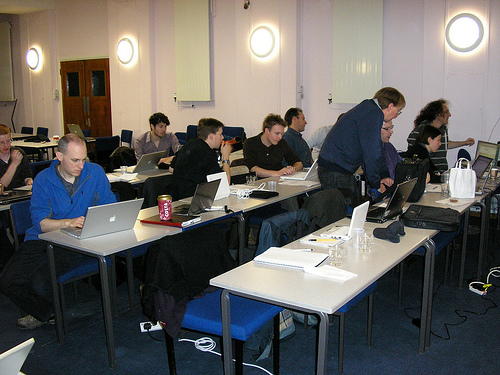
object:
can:
[156, 193, 174, 222]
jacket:
[296, 186, 349, 230]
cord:
[176, 335, 271, 374]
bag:
[446, 157, 477, 202]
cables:
[467, 278, 490, 295]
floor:
[4, 218, 499, 373]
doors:
[82, 57, 115, 137]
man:
[6, 133, 118, 331]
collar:
[280, 220, 309, 240]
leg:
[315, 317, 329, 375]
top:
[206, 218, 442, 317]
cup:
[487, 166, 497, 183]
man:
[133, 113, 178, 172]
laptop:
[320, 200, 369, 244]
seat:
[153, 286, 285, 373]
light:
[244, 20, 279, 66]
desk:
[206, 216, 438, 372]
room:
[0, 0, 499, 374]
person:
[378, 118, 406, 185]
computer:
[110, 150, 164, 175]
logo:
[107, 214, 119, 224]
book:
[140, 211, 202, 230]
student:
[281, 107, 313, 168]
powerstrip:
[135, 320, 163, 334]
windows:
[86, 69, 107, 99]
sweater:
[22, 161, 116, 244]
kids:
[241, 112, 306, 181]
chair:
[407, 227, 461, 258]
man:
[316, 85, 405, 209]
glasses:
[391, 106, 402, 113]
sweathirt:
[383, 143, 403, 182]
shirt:
[241, 133, 287, 177]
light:
[115, 33, 142, 71]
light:
[24, 43, 46, 74]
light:
[436, 6, 489, 60]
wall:
[298, 0, 420, 156]